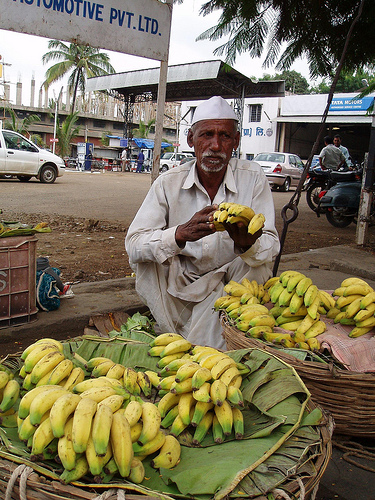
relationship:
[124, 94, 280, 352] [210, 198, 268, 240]
man holding bananas